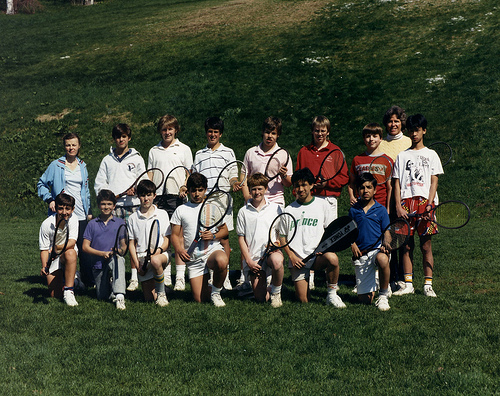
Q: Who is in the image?
A: Boys.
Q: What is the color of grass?
A: Green.